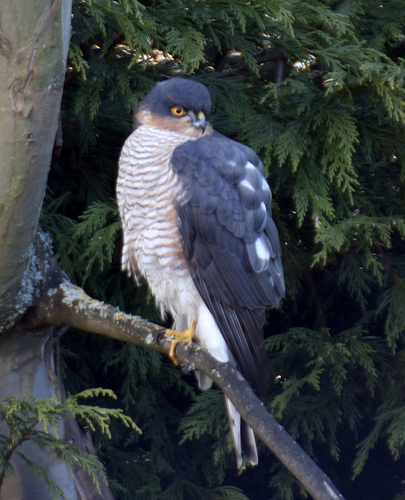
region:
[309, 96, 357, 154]
green of tree branch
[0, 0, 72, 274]
bark on surface of tree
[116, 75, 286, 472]
bird standing on branch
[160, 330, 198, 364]
yellow claws on wood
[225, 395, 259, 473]
tail feathers of bird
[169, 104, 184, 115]
yellow eye with black pupil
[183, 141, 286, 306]
feathers of bird wing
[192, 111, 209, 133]
curved beak of bird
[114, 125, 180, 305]
white and tan feathers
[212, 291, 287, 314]
edge of bird wing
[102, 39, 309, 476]
bird perched on branch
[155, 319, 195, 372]
bird's talons gripping branch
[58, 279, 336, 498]
branch bird is perched on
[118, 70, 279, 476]
gray and white bird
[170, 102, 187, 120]
yellow and black eye of bird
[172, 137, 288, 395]
dark gray feathers of bird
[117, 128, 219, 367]
white chest of bird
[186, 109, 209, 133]
beak of gray and white bird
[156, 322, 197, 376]
orange and black foot of bird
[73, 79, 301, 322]
bird on the branch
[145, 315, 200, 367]
foot on the branch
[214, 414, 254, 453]
tail feather of the bird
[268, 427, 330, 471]
branch under the bird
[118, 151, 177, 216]
chest of the bird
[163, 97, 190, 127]
eye of the bird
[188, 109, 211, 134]
beak of the bird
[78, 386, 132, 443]
green branch next to the bird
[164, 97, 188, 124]
yellow eye of the bird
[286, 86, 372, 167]
tree behind the bird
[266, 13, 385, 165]
Green boughs of a tree.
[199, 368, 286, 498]
Branch of a tree.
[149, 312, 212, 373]
Claws of a bird.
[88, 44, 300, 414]
A bird perched on a branch.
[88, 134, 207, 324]
Ruffled breast of a bird.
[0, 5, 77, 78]
Trunk of a tree.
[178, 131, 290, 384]
Feathers of a bird.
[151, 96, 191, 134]
Small eye of a bird.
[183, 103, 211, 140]
Beak of a bird.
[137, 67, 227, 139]
Head of a bird.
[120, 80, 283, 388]
grey and white hawk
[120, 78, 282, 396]
bird sitting on branch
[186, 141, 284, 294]
grey wing on bird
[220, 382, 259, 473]
grey and white birds tail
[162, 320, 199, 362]
yellow foot of bird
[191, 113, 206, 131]
grey beak on bird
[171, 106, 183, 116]
yellow eye of bird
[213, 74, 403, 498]
green branches of tree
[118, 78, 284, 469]
hawk sitting on branch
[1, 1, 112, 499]
grey wood tree trunk